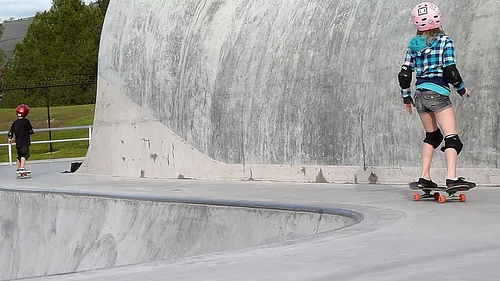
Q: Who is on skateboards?
A: Two kids.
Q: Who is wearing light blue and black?
A: Girl.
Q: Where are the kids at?
A: Skate park.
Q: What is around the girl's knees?
A: Knee pads.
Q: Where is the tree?
A: Behind the fence.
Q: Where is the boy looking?
A: Past the fence.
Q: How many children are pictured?
A: Two.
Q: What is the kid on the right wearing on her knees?
A: Knee pads.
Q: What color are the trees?
A: Green.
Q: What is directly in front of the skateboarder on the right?
A: Wall.